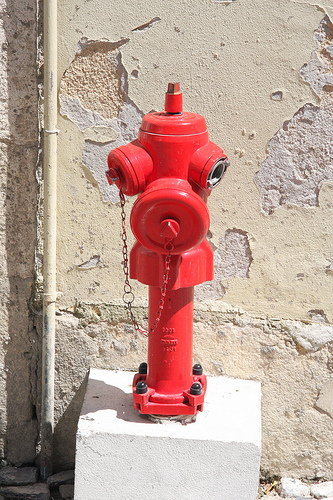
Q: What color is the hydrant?
A: Red.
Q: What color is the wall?
A: White.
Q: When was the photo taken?
A: Daytime.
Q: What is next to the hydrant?
A: A wall.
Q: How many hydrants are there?
A: One.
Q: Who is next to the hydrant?
A: No one.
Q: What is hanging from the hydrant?
A: A chain.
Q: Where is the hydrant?
A: On a street.